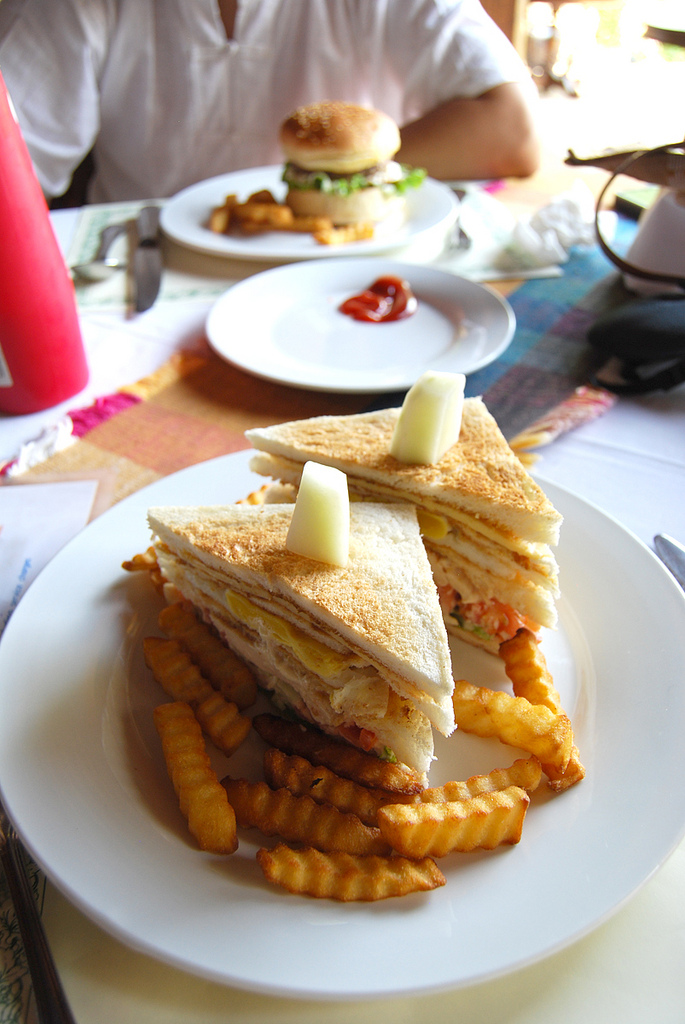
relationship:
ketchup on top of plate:
[353, 275, 406, 324] [265, 324, 461, 372]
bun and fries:
[279, 85, 396, 236] [264, 773, 460, 852]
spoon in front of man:
[80, 220, 116, 283] [90, 6, 532, 153]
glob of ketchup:
[363, 276, 421, 311] [353, 275, 406, 324]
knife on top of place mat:
[136, 220, 151, 300] [185, 262, 227, 301]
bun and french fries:
[279, 85, 396, 236] [210, 184, 293, 225]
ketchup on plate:
[353, 275, 406, 324] [265, 324, 461, 372]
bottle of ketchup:
[6, 269, 92, 408] [353, 275, 406, 324]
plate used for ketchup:
[265, 324, 461, 372] [353, 275, 406, 324]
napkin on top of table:
[478, 212, 531, 277] [593, 450, 655, 477]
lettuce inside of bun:
[283, 168, 332, 189] [279, 85, 396, 236]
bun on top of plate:
[279, 85, 396, 236] [265, 324, 461, 372]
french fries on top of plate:
[210, 184, 293, 225] [265, 324, 461, 372]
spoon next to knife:
[80, 220, 116, 283] [136, 220, 151, 300]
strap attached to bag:
[589, 232, 627, 260] [640, 157, 676, 300]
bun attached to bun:
[279, 119, 395, 185] [279, 85, 396, 236]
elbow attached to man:
[426, 84, 530, 174] [90, 6, 532, 153]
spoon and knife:
[80, 220, 116, 283] [136, 220, 151, 300]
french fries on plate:
[210, 184, 293, 225] [265, 324, 461, 372]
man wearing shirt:
[90, 6, 532, 153] [29, 73, 151, 160]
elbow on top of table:
[426, 84, 530, 174] [593, 450, 655, 477]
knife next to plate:
[136, 220, 151, 300] [265, 324, 461, 372]